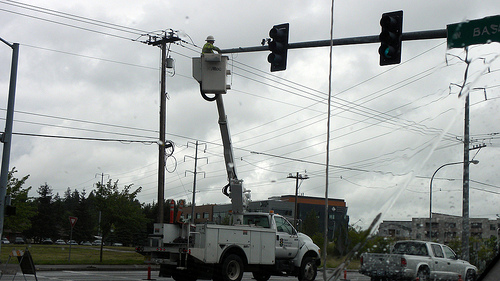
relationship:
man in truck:
[201, 32, 224, 58] [135, 54, 320, 281]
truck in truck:
[135, 54, 320, 281] [156, 197, 317, 280]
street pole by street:
[151, 54, 177, 197] [102, 271, 147, 273]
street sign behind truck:
[440, 4, 494, 63] [135, 54, 320, 281]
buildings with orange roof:
[285, 191, 350, 275] [275, 188, 365, 213]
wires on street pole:
[9, 1, 150, 57] [151, 54, 177, 197]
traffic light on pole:
[263, 7, 307, 84] [294, 34, 375, 63]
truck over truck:
[135, 54, 320, 281] [156, 197, 317, 280]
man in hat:
[201, 32, 224, 58] [203, 37, 219, 43]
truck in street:
[156, 197, 317, 280] [102, 271, 147, 273]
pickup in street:
[356, 224, 487, 280] [102, 271, 147, 273]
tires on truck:
[280, 251, 332, 279] [156, 197, 317, 280]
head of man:
[203, 42, 217, 44] [201, 32, 224, 58]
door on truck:
[276, 230, 300, 256] [156, 197, 317, 280]